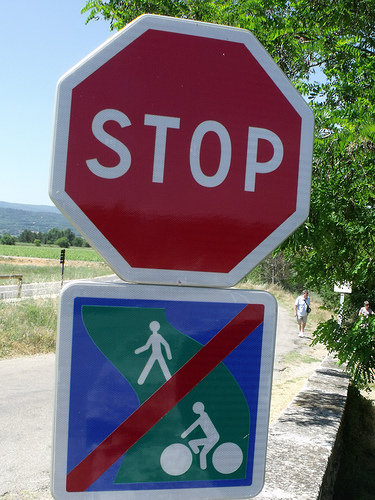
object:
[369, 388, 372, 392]
green leaves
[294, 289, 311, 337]
person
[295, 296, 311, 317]
white shirt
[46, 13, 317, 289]
sign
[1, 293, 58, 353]
grass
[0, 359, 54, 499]
sidewalk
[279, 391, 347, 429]
shadow